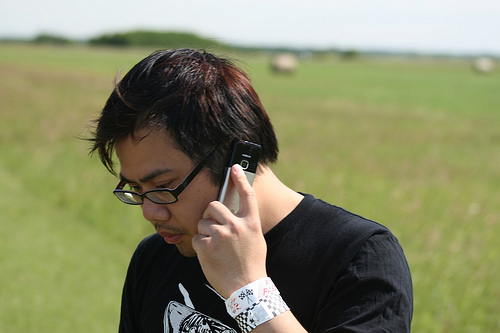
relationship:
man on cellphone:
[86, 49, 413, 331] [213, 140, 265, 214]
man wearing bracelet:
[86, 49, 413, 331] [224, 279, 290, 333]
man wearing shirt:
[86, 49, 413, 331] [113, 190, 414, 332]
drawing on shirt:
[162, 283, 240, 332] [113, 190, 414, 332]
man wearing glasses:
[86, 49, 413, 331] [113, 138, 224, 206]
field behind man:
[1, 41, 500, 333] [86, 49, 413, 331]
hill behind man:
[95, 29, 226, 44] [86, 49, 413, 331]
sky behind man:
[1, 0, 500, 55] [86, 49, 413, 331]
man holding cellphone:
[86, 49, 413, 331] [213, 140, 265, 214]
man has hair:
[86, 49, 413, 331] [92, 49, 280, 184]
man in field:
[86, 49, 413, 331] [1, 41, 500, 333]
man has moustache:
[86, 49, 413, 331] [151, 223, 188, 237]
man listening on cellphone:
[86, 49, 413, 331] [213, 140, 265, 214]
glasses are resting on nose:
[113, 138, 224, 206] [142, 188, 169, 225]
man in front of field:
[86, 49, 413, 331] [1, 41, 500, 333]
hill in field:
[95, 29, 226, 44] [1, 41, 500, 333]